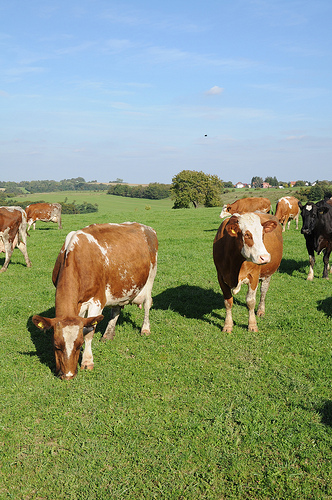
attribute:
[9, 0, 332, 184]
sky — clear, blue, cloudy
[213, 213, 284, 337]
cow — brown, white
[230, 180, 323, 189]
buildings — distant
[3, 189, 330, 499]
grass — here, green, short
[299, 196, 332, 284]
cow — dark brown, black, white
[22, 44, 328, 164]
clouds — thin, white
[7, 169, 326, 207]
trees — tall, distant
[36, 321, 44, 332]
tag — yellow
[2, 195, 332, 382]
cattle — grazing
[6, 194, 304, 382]
cattle — brown, white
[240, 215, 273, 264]
face — white